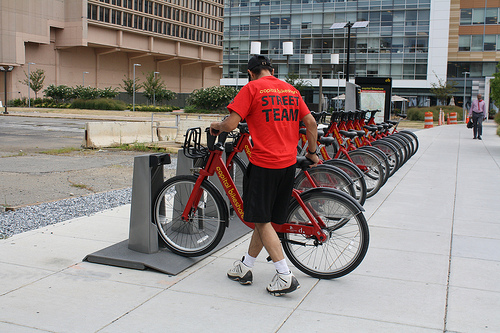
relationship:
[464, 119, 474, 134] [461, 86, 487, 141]
bag in hand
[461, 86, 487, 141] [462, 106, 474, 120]
hand of man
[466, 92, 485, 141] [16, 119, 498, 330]
man walking down sidewalk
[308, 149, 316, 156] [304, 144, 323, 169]
watch on wrist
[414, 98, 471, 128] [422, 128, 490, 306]
traffic cones at end of sidewalk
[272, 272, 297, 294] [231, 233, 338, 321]
shoes on feet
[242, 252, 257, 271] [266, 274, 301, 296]
white sock on foot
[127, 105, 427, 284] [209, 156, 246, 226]
bikes with letters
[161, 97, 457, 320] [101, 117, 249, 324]
bike in rack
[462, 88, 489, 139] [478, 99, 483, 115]
man wearing tie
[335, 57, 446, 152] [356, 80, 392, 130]
display on large map